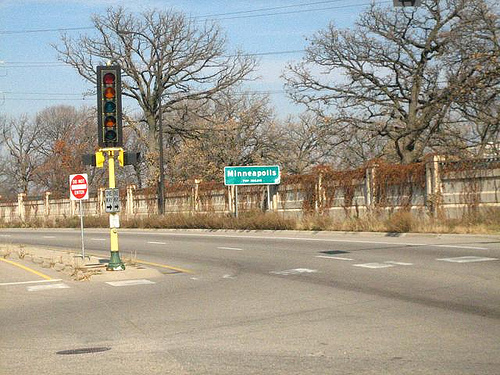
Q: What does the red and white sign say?
A: Do not enter.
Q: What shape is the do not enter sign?
A: Square.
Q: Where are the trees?
A: Behind the concrete wall.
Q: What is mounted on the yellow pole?
A: A traffic signal.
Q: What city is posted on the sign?
A: Minneapolis.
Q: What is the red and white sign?
A: Do Not Enter.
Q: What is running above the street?
A: Power lines.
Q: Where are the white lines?
A: On the road.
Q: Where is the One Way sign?
A: On the pole.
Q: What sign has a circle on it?
A: Do Not Enter sign.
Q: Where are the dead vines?
A: Climbing the walls.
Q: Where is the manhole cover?
A: In the lower left corner.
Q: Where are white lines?
A: On the road.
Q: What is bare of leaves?
A: The trees.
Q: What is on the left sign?
A: Do Not Enter.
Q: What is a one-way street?
A: To the right.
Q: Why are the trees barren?
A: It is not spring yet.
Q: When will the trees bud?
A: Weather is warmer.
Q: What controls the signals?
A: Clocks.